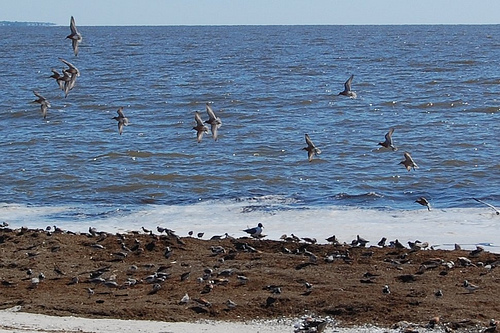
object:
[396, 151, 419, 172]
bird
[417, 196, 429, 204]
wings open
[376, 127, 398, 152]
bird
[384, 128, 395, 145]
wings overhead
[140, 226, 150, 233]
white bird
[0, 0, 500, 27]
clouds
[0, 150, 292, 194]
ripples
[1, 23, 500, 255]
water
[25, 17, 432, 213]
group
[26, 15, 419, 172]
birds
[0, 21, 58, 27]
pier